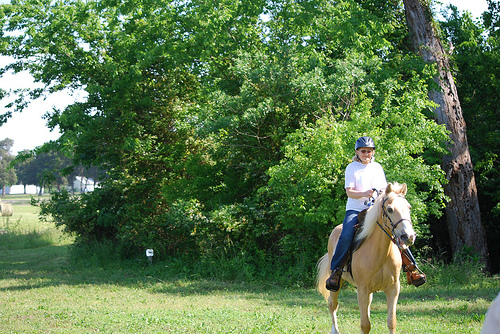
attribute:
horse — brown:
[314, 180, 428, 332]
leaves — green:
[169, 162, 224, 218]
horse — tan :
[314, 177, 416, 330]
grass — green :
[97, 276, 229, 318]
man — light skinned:
[325, 148, 385, 205]